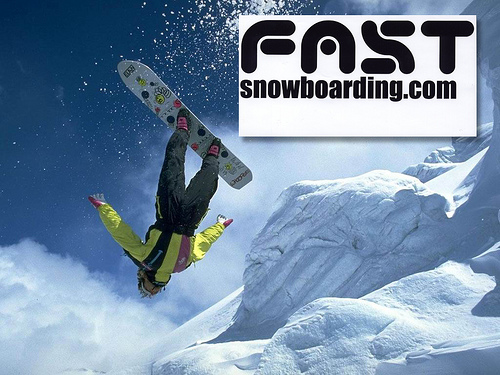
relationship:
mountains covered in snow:
[142, 3, 499, 374] [140, 2, 499, 374]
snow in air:
[5, 1, 348, 171] [1, 2, 475, 329]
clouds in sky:
[3, 119, 498, 375] [2, 2, 495, 326]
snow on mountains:
[140, 2, 499, 374] [142, 3, 499, 374]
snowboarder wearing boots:
[87, 110, 234, 298] [176, 108, 220, 155]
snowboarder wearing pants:
[87, 110, 234, 298] [154, 128, 222, 234]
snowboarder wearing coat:
[87, 110, 234, 298] [97, 205, 225, 282]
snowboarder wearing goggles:
[87, 110, 234, 298] [137, 278, 164, 297]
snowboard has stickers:
[115, 60, 254, 190] [134, 76, 242, 176]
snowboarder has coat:
[87, 110, 234, 298] [97, 205, 225, 282]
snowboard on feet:
[115, 60, 254, 190] [169, 108, 224, 161]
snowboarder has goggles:
[87, 110, 234, 298] [137, 278, 164, 297]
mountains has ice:
[142, 3, 499, 374] [149, 2, 495, 374]